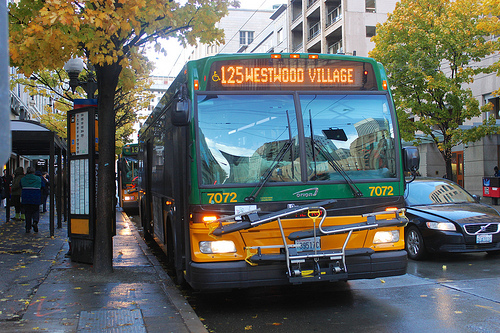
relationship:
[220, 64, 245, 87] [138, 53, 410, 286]
number 125 on bus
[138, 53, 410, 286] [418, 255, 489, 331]
bus on road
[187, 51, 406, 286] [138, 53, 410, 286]
front on bus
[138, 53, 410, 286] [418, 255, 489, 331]
bus in road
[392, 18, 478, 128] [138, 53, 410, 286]
tree near bus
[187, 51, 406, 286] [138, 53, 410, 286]
front of bus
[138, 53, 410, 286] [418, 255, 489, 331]
bus near road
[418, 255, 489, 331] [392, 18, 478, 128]
road near tree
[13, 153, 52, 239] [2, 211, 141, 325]
man walking down sidewalk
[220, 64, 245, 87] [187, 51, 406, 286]
number 125 on front